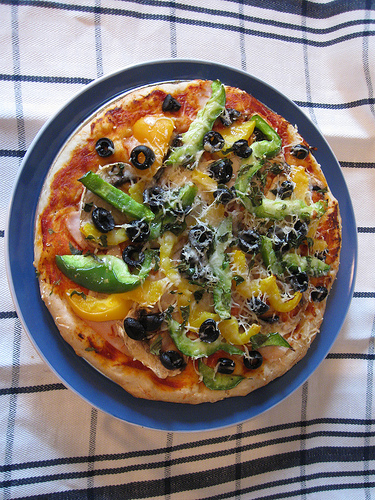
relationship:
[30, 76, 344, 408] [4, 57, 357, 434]
pizza sitting on dish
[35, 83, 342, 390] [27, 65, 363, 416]
sauce on pizza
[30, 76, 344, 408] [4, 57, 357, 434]
pizza on dish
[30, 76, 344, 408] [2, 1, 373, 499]
pizza on cloth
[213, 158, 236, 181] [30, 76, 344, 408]
olive on pizza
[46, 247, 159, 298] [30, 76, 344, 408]
green pepper on pizza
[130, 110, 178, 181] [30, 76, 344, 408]
pepper on pizza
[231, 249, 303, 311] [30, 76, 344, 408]
pepper on pizza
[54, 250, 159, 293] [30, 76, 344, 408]
pepper on pizza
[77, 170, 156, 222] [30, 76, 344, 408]
pepper on pizza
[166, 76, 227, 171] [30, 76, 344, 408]
pepper on pizza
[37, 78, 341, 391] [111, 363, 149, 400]
sauce on crust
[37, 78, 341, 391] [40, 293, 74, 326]
sauce on crust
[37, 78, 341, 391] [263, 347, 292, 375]
sauce on crust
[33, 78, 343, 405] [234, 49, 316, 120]
pizza on dish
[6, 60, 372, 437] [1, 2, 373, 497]
dish on tablecloth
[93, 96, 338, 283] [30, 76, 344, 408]
slice pepper on pizza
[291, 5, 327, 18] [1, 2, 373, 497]
lines on tablecloth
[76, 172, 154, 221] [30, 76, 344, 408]
green pepper on pizza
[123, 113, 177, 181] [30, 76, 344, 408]
pepper on pizza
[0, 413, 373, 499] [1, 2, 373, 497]
black line on tablecloth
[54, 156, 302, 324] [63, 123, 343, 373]
cheese on pizza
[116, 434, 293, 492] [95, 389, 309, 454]
table cloth under plate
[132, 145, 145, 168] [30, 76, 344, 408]
anchovie on pizza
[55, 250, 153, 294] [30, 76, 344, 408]
pepper on pizza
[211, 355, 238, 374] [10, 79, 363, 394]
olive on top of pizza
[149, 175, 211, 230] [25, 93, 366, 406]
cheese on pizza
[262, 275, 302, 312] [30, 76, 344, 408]
yellow pepper on pizza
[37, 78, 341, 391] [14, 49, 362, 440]
sauce on pizza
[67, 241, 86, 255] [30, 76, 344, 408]
fresh basil on pizza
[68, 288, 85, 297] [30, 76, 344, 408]
fresh basil on pizza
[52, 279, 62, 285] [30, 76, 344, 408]
fresh basil on pizza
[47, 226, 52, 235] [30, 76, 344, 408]
fresh basil on pizza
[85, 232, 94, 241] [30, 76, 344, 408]
fresh basil on pizza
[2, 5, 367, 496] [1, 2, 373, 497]
stripes on tablecloth